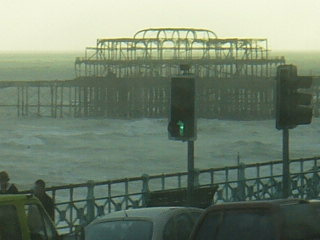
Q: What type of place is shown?
A: It is an ocean.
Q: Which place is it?
A: It is an ocean.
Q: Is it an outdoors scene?
A: Yes, it is outdoors.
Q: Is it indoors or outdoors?
A: It is outdoors.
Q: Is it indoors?
A: No, it is outdoors.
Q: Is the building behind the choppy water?
A: Yes, the building is behind the water.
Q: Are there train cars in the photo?
A: No, there are no train cars.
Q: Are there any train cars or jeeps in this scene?
A: No, there are no train cars or jeeps.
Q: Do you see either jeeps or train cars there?
A: No, there are no train cars or jeeps.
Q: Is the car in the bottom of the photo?
A: Yes, the car is in the bottom of the image.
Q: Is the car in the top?
A: No, the car is in the bottom of the image.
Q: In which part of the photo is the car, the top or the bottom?
A: The car is in the bottom of the image.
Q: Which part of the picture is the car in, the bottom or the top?
A: The car is in the bottom of the image.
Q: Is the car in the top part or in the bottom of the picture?
A: The car is in the bottom of the image.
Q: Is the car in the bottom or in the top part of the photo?
A: The car is in the bottom of the image.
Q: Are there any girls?
A: No, there are no girls.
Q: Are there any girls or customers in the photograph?
A: No, there are no girls or customers.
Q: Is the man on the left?
A: Yes, the man is on the left of the image.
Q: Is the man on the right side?
A: No, the man is on the left of the image.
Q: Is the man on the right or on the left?
A: The man is on the left of the image.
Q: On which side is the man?
A: The man is on the left of the image.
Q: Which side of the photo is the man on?
A: The man is on the left of the image.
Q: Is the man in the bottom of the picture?
A: Yes, the man is in the bottom of the image.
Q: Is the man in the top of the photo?
A: No, the man is in the bottom of the image.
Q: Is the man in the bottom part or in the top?
A: The man is in the bottom of the image.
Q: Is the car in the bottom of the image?
A: Yes, the car is in the bottom of the image.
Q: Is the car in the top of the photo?
A: No, the car is in the bottom of the image.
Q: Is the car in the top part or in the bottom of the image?
A: The car is in the bottom of the image.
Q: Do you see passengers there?
A: No, there are no passengers.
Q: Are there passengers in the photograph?
A: No, there are no passengers.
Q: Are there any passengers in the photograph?
A: No, there are no passengers.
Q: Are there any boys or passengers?
A: No, there are no passengers or boys.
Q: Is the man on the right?
A: No, the man is on the left of the image.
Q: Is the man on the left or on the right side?
A: The man is on the left of the image.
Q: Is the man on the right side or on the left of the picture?
A: The man is on the left of the image.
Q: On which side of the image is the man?
A: The man is on the left of the image.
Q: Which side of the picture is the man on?
A: The man is on the left of the image.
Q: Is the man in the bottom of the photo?
A: Yes, the man is in the bottom of the image.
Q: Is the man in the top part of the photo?
A: No, the man is in the bottom of the image.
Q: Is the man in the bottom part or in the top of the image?
A: The man is in the bottom of the image.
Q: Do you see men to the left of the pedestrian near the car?
A: Yes, there is a man to the left of the pedestrian.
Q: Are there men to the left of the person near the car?
A: Yes, there is a man to the left of the pedestrian.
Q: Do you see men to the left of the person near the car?
A: Yes, there is a man to the left of the pedestrian.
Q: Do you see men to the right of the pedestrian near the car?
A: No, the man is to the left of the pedestrian.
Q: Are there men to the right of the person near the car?
A: No, the man is to the left of the pedestrian.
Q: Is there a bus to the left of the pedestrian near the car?
A: No, there is a man to the left of the pedestrian.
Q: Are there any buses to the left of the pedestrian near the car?
A: No, there is a man to the left of the pedestrian.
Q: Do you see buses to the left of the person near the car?
A: No, there is a man to the left of the pedestrian.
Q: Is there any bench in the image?
A: Yes, there is a bench.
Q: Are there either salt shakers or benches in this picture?
A: Yes, there is a bench.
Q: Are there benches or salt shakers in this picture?
A: Yes, there is a bench.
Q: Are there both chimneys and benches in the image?
A: No, there is a bench but no chimneys.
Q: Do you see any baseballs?
A: No, there are no baseballs.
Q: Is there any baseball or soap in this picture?
A: No, there are no baseballs or soaps.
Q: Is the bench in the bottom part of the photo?
A: Yes, the bench is in the bottom of the image.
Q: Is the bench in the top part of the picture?
A: No, the bench is in the bottom of the image.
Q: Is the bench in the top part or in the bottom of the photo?
A: The bench is in the bottom of the image.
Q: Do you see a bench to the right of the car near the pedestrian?
A: Yes, there is a bench to the right of the car.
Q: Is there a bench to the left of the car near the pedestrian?
A: No, the bench is to the right of the car.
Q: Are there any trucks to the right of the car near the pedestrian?
A: No, there is a bench to the right of the car.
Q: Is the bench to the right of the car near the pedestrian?
A: Yes, the bench is to the right of the car.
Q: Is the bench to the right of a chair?
A: No, the bench is to the right of the car.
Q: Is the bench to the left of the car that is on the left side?
A: No, the bench is to the right of the car.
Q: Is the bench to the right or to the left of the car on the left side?
A: The bench is to the right of the car.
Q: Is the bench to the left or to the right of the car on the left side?
A: The bench is to the right of the car.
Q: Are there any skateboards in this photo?
A: No, there are no skateboards.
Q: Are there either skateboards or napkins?
A: No, there are no skateboards or napkins.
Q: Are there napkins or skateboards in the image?
A: No, there are no skateboards or napkins.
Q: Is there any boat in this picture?
A: No, there are no boats.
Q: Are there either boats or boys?
A: No, there are no boats or boys.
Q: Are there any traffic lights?
A: Yes, there is a traffic light.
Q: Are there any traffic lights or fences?
A: Yes, there is a traffic light.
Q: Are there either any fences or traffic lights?
A: Yes, there is a traffic light.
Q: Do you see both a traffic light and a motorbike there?
A: No, there is a traffic light but no motorcycles.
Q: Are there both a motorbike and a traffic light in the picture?
A: No, there is a traffic light but no motorcycles.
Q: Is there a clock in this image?
A: No, there are no clocks.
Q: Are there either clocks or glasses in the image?
A: No, there are no clocks or glasses.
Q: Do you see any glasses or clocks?
A: No, there are no clocks or glasses.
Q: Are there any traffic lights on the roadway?
A: Yes, there is a traffic light on the roadway.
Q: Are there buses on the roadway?
A: No, there is a traffic light on the roadway.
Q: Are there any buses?
A: No, there are no buses.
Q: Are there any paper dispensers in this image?
A: No, there are no paper dispensers.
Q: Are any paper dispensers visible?
A: No, there are no paper dispensers.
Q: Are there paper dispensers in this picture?
A: No, there are no paper dispensers.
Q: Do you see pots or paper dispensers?
A: No, there are no paper dispensers or pots.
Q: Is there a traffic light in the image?
A: Yes, there is a traffic light.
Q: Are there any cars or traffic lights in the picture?
A: Yes, there is a traffic light.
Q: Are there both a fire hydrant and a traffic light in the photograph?
A: No, there is a traffic light but no fire hydrants.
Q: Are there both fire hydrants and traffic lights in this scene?
A: No, there is a traffic light but no fire hydrants.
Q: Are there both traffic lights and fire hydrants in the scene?
A: No, there is a traffic light but no fire hydrants.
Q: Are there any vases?
A: No, there are no vases.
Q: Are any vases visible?
A: No, there are no vases.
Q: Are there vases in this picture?
A: No, there are no vases.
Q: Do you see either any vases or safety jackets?
A: No, there are no vases or safety jackets.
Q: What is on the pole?
A: The traffic light is on the pole.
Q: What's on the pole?
A: The traffic light is on the pole.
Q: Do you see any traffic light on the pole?
A: Yes, there is a traffic light on the pole.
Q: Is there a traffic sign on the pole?
A: No, there is a traffic light on the pole.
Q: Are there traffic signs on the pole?
A: No, there is a traffic light on the pole.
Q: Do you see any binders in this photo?
A: No, there are no binders.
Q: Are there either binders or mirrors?
A: No, there are no binders or mirrors.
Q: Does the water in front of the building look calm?
A: No, the water is choppy.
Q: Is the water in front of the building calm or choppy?
A: The water is choppy.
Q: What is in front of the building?
A: The water is in front of the building.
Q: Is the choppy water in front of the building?
A: Yes, the water is in front of the building.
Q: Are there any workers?
A: No, there are no workers.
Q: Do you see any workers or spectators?
A: No, there are no workers or spectators.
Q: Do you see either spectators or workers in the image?
A: No, there are no workers or spectators.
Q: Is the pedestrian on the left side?
A: Yes, the pedestrian is on the left of the image.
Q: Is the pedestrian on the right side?
A: No, the pedestrian is on the left of the image.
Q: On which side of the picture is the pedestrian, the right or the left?
A: The pedestrian is on the left of the image.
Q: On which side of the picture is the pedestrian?
A: The pedestrian is on the left of the image.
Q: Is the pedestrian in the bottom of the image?
A: Yes, the pedestrian is in the bottom of the image.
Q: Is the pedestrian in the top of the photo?
A: No, the pedestrian is in the bottom of the image.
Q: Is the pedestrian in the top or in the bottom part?
A: The pedestrian is in the bottom of the image.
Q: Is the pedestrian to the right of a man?
A: Yes, the pedestrian is to the right of a man.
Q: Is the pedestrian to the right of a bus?
A: No, the pedestrian is to the right of a man.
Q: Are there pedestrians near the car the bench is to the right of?
A: Yes, there is a pedestrian near the car.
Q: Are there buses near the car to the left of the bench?
A: No, there is a pedestrian near the car.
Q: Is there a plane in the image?
A: No, there are no airplanes.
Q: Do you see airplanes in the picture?
A: No, there are no airplanes.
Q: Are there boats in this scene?
A: No, there are no boats.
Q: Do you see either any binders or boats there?
A: No, there are no boats or binders.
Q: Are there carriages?
A: No, there are no carriages.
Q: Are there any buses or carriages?
A: No, there are no carriages or buses.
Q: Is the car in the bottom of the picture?
A: Yes, the car is in the bottom of the image.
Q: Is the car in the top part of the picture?
A: No, the car is in the bottom of the image.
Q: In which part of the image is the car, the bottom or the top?
A: The car is in the bottom of the image.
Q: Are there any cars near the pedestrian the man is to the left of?
A: Yes, there is a car near the pedestrian.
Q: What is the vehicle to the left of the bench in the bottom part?
A: The vehicle is a car.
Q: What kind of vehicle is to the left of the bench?
A: The vehicle is a car.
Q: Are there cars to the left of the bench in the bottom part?
A: Yes, there is a car to the left of the bench.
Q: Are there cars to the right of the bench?
A: No, the car is to the left of the bench.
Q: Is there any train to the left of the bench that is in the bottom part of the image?
A: No, there is a car to the left of the bench.